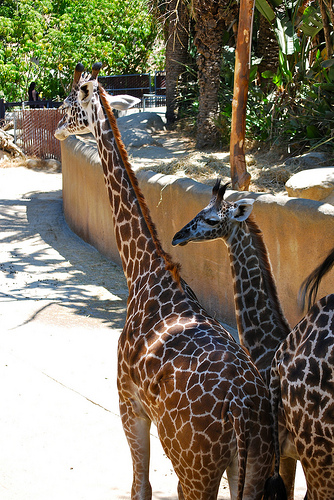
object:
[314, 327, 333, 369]
brown spots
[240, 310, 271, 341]
brown spots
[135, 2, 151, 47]
trees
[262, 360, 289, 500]
tail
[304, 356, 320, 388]
spot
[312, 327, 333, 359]
spot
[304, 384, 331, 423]
spot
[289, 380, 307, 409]
spot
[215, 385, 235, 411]
spots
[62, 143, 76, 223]
wall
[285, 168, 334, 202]
rock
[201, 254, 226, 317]
wall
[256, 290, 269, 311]
spot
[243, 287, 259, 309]
spot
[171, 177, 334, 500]
giraffe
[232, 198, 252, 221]
ear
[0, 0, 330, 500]
zoo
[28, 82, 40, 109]
person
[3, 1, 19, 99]
trees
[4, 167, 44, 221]
ground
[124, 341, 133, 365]
spots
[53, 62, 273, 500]
giraffe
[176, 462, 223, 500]
back/left leg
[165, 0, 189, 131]
tree trunk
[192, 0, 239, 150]
palm tree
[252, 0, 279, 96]
palm tree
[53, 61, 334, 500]
three giraffes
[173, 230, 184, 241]
nose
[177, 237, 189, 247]
mouth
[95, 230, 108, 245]
wall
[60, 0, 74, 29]
trees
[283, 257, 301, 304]
wall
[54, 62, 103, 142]
head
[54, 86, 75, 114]
area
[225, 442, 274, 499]
leg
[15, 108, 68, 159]
fence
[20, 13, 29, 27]
leaves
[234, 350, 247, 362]
spots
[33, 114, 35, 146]
lattice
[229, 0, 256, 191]
tree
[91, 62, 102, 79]
horn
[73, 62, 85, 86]
horn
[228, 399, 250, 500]
tail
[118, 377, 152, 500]
leg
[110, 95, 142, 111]
ear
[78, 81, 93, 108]
ear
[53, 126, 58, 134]
nose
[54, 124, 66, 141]
mouth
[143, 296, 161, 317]
spot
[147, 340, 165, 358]
spot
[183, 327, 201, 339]
spot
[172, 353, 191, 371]
spot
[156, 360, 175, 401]
spot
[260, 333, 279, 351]
spot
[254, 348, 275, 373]
spot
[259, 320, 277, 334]
spot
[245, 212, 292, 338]
mane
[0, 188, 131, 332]
shadows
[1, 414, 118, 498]
ground